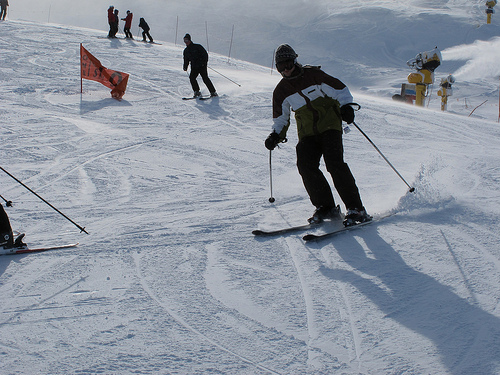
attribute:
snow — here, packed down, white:
[142, 249, 298, 324]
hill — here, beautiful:
[28, 23, 71, 101]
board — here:
[310, 236, 328, 243]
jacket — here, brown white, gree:
[263, 68, 358, 140]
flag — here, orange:
[71, 46, 134, 98]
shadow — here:
[318, 221, 498, 364]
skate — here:
[46, 242, 81, 252]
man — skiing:
[261, 46, 372, 223]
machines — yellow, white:
[397, 48, 459, 111]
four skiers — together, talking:
[102, 3, 154, 46]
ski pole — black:
[10, 166, 94, 235]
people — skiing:
[4, 7, 423, 270]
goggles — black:
[273, 58, 296, 69]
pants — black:
[289, 133, 367, 214]